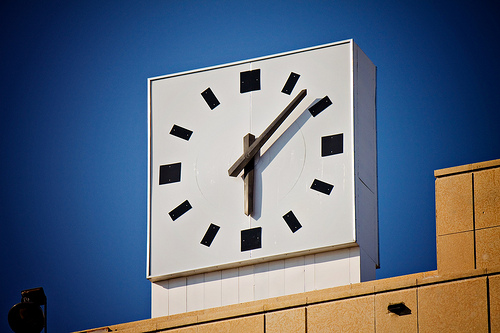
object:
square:
[159, 162, 182, 185]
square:
[169, 124, 193, 141]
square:
[240, 227, 262, 252]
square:
[200, 223, 220, 247]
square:
[167, 200, 193, 222]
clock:
[145, 39, 356, 280]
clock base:
[149, 247, 375, 319]